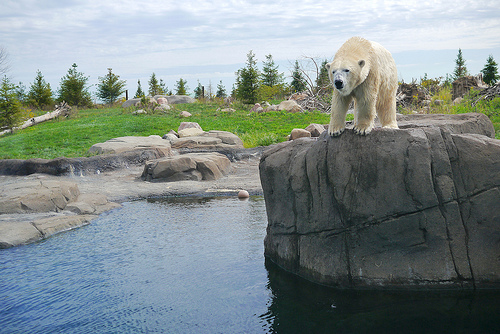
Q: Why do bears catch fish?
A: To eat.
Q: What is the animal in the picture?
A: Bear.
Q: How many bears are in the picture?
A: One.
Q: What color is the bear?
A: White.